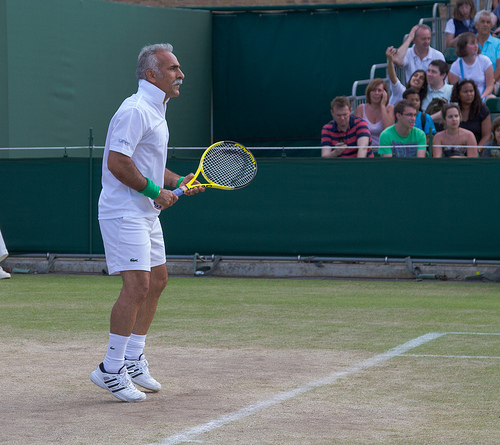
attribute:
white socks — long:
[106, 326, 149, 361]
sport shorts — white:
[96, 213, 166, 276]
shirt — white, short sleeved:
[107, 91, 170, 201]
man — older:
[88, 42, 203, 402]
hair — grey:
[135, 41, 172, 82]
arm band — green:
[142, 171, 163, 207]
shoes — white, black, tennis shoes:
[92, 360, 147, 404]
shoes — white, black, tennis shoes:
[126, 356, 161, 394]